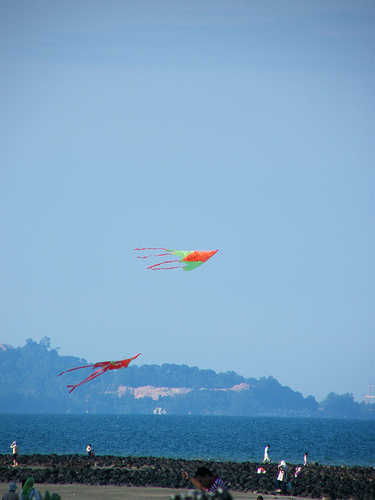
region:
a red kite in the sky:
[58, 350, 150, 391]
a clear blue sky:
[239, 290, 359, 361]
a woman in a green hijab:
[22, 478, 61, 497]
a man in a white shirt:
[7, 440, 31, 471]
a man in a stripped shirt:
[193, 462, 232, 498]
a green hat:
[0, 477, 18, 494]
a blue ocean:
[159, 417, 372, 444]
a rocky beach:
[102, 454, 179, 488]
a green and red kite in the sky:
[141, 236, 233, 294]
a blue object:
[283, 476, 297, 492]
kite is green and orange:
[132, 243, 220, 273]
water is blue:
[0, 410, 373, 471]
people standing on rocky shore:
[0, 438, 373, 498]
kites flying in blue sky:
[0, 0, 374, 402]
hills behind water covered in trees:
[1, 335, 373, 419]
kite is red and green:
[53, 351, 142, 393]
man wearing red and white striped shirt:
[178, 465, 229, 496]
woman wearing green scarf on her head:
[19, 475, 39, 499]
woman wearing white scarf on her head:
[272, 458, 292, 496]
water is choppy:
[0, 411, 373, 467]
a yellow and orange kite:
[135, 246, 219, 272]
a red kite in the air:
[55, 353, 141, 393]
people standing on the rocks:
[9, 441, 309, 492]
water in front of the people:
[0, 409, 373, 465]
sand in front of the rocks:
[1, 483, 309, 498]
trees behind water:
[0, 339, 373, 417]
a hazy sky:
[0, 0, 373, 401]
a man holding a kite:
[181, 466, 228, 498]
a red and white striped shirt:
[207, 475, 227, 496]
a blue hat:
[8, 481, 16, 490]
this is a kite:
[115, 231, 228, 301]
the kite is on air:
[128, 239, 222, 280]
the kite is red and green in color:
[129, 237, 221, 285]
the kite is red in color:
[53, 346, 143, 394]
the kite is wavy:
[56, 347, 142, 395]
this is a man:
[260, 443, 275, 460]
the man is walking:
[261, 444, 274, 462]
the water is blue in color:
[126, 413, 251, 450]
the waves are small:
[164, 419, 240, 453]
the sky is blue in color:
[256, 1, 367, 349]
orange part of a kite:
[198, 253, 203, 259]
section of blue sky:
[214, 287, 255, 320]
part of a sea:
[185, 417, 205, 433]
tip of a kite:
[217, 249, 221, 253]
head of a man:
[199, 476, 208, 481]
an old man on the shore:
[12, 444, 17, 468]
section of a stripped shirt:
[219, 480, 223, 490]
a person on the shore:
[263, 447, 271, 459]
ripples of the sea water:
[190, 429, 220, 452]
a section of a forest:
[172, 364, 193, 379]